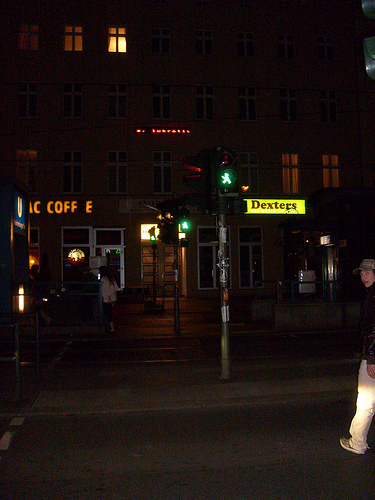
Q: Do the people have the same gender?
A: No, they are both male and female.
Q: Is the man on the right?
A: Yes, the man is on the right of the image.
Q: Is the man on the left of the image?
A: No, the man is on the right of the image.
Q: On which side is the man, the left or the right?
A: The man is on the right of the image.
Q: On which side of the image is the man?
A: The man is on the right of the image.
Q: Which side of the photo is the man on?
A: The man is on the right of the image.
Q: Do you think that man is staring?
A: Yes, the man is staring.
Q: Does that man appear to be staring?
A: Yes, the man is staring.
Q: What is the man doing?
A: The man is staring.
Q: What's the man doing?
A: The man is staring.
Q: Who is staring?
A: The man is staring.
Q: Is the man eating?
A: No, the man is staring.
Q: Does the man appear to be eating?
A: No, the man is staring.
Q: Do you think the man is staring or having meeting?
A: The man is staring.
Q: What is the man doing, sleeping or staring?
A: The man is staring.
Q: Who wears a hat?
A: The man wears a hat.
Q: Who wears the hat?
A: The man wears a hat.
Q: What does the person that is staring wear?
A: The man wears a hat.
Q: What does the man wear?
A: The man wears a hat.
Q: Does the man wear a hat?
A: Yes, the man wears a hat.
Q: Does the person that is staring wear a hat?
A: Yes, the man wears a hat.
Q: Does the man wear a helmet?
A: No, the man wears a hat.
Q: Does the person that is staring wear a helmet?
A: No, the man wears a hat.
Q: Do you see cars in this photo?
A: No, there are no cars.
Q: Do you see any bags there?
A: No, there are no bags.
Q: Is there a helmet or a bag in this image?
A: No, there are no bags or helmets.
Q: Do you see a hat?
A: Yes, there is a hat.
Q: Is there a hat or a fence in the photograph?
A: Yes, there is a hat.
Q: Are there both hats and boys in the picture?
A: No, there is a hat but no boys.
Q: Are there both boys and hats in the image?
A: No, there is a hat but no boys.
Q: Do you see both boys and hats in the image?
A: No, there is a hat but no boys.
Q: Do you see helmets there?
A: No, there are no helmets.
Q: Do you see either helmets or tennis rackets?
A: No, there are no helmets or tennis rackets.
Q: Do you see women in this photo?
A: Yes, there is a woman.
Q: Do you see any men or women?
A: Yes, there is a woman.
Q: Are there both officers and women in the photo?
A: No, there is a woman but no officers.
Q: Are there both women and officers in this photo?
A: No, there is a woman but no officers.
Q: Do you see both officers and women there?
A: No, there is a woman but no officers.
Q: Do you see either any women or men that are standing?
A: Yes, the woman is standing.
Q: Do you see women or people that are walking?
A: Yes, the woman is walking.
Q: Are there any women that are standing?
A: Yes, there is a woman that is standing.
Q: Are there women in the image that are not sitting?
A: Yes, there is a woman that is standing.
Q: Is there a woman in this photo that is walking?
A: Yes, there is a woman that is walking.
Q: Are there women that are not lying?
A: Yes, there is a woman that is walking.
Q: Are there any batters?
A: No, there are no batters.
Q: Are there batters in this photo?
A: No, there are no batters.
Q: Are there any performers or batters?
A: No, there are no batters or performers.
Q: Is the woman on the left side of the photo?
A: Yes, the woman is on the left of the image.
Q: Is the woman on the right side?
A: No, the woman is on the left of the image.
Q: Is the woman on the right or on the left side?
A: The woman is on the left of the image.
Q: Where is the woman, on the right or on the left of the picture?
A: The woman is on the left of the image.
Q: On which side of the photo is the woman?
A: The woman is on the left of the image.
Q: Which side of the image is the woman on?
A: The woman is on the left of the image.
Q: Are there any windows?
A: Yes, there is a window.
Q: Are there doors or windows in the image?
A: Yes, there is a window.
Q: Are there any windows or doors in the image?
A: Yes, there is a window.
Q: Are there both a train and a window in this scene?
A: No, there is a window but no trains.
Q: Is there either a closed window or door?
A: Yes, there is a closed window.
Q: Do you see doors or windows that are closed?
A: Yes, the window is closed.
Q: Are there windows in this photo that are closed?
A: Yes, there is a closed window.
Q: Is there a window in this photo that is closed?
A: Yes, there is a window that is closed.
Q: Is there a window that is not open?
A: Yes, there is an closed window.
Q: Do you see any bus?
A: No, there are no buses.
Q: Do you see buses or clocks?
A: No, there are no buses or clocks.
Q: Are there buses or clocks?
A: No, there are no buses or clocks.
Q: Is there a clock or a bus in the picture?
A: No, there are no buses or clocks.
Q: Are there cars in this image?
A: No, there are no cars.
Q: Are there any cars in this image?
A: No, there are no cars.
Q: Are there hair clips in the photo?
A: No, there are no hair clips.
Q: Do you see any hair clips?
A: No, there are no hair clips.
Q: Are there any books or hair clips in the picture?
A: No, there are no hair clips or books.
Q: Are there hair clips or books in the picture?
A: No, there are no hair clips or books.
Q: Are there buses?
A: No, there are no buses.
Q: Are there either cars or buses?
A: No, there are no buses or cars.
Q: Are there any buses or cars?
A: No, there are no buses or cars.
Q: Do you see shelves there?
A: No, there are no shelves.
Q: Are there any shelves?
A: No, there are no shelves.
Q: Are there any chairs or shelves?
A: No, there are no shelves or chairs.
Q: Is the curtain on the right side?
A: Yes, the curtain is on the right of the image.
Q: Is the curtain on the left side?
A: No, the curtain is on the right of the image.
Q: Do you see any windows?
A: Yes, there is a window.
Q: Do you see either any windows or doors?
A: Yes, there is a window.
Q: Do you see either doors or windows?
A: Yes, there is a window.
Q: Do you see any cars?
A: No, there are no cars.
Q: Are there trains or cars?
A: No, there are no cars or trains.